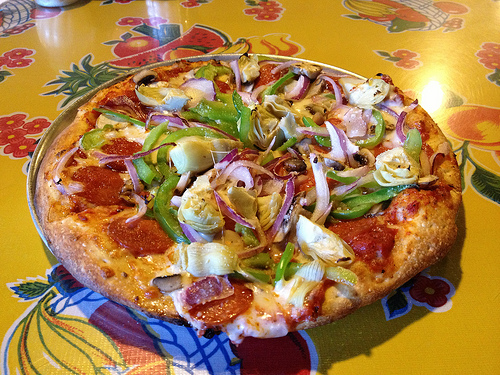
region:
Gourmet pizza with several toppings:
[25, 52, 458, 338]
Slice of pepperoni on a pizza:
[177, 277, 252, 326]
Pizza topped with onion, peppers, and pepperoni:
[27, 52, 459, 334]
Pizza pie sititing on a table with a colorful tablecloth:
[0, 0, 498, 373]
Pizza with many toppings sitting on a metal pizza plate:
[26, 52, 462, 336]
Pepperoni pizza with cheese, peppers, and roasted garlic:
[26, 52, 458, 340]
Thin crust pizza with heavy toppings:
[24, 51, 461, 335]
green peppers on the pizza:
[153, 186, 183, 201]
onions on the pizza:
[310, 163, 334, 195]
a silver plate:
[38, 132, 60, 142]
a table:
[393, 20, 472, 70]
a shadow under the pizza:
[361, 303, 393, 343]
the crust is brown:
[411, 220, 446, 240]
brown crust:
[411, 223, 451, 247]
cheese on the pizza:
[253, 321, 289, 334]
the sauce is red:
[356, 235, 382, 257]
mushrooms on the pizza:
[353, 77, 385, 102]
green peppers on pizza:
[128, 93, 275, 278]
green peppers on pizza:
[127, 109, 202, 260]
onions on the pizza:
[220, 132, 309, 263]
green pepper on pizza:
[150, 173, 184, 244]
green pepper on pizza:
[261, 229, 316, 316]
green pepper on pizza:
[332, 189, 374, 220]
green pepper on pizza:
[348, 171, 416, 203]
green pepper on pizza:
[231, 101, 269, 146]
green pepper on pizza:
[194, 96, 245, 137]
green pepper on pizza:
[124, 115, 166, 153]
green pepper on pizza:
[55, 122, 126, 152]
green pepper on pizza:
[85, 83, 133, 133]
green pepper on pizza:
[194, 56, 245, 101]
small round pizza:
[19, 23, 441, 341]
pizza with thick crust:
[45, 50, 483, 321]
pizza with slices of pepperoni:
[28, 33, 428, 300]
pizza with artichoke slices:
[61, 62, 428, 357]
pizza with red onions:
[41, 12, 443, 327]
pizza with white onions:
[57, 32, 438, 332]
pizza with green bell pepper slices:
[50, 42, 435, 324]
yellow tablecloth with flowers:
[3, 7, 483, 358]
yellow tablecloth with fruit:
[8, 5, 488, 357]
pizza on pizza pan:
[27, 39, 448, 314]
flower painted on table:
[406, 275, 455, 312]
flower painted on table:
[394, 55, 421, 69]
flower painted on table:
[392, 46, 419, 60]